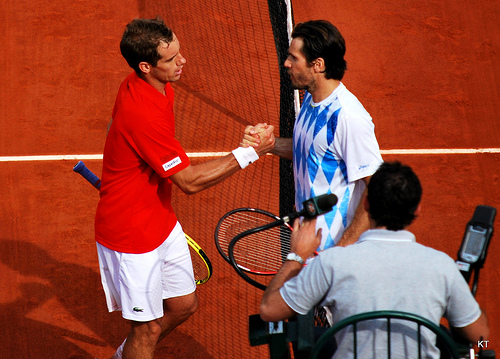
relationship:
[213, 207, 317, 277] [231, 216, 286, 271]
racket has part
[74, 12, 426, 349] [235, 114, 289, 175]
players shaking hands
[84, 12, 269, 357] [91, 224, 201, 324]
player wears shorts